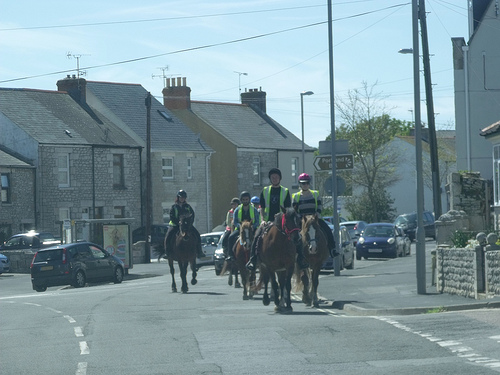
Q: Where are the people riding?
A: Street.